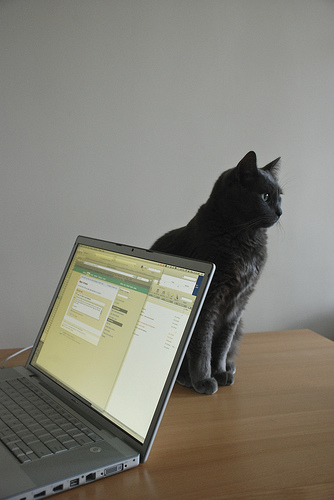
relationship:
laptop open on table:
[0, 222, 216, 491] [2, 327, 332, 499]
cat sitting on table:
[145, 149, 287, 397] [2, 327, 332, 499]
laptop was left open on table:
[0, 222, 216, 491] [2, 327, 332, 499]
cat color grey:
[145, 149, 287, 397] [141, 151, 284, 408]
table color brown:
[2, 327, 332, 499] [2, 327, 329, 495]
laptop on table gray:
[0, 222, 216, 491] [4, 374, 105, 473]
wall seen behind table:
[5, 8, 333, 339] [2, 327, 332, 499]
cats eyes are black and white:
[145, 149, 287, 397] [259, 192, 284, 204]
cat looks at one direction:
[145, 149, 287, 397] [212, 149, 298, 233]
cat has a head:
[145, 149, 287, 397] [210, 150, 291, 227]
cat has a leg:
[145, 149, 287, 397] [183, 307, 219, 398]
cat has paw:
[145, 149, 287, 397] [192, 377, 221, 395]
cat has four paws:
[145, 149, 287, 397] [181, 364, 236, 397]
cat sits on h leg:
[145, 149, 287, 397] [183, 307, 219, 398]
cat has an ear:
[145, 149, 287, 397] [237, 147, 259, 180]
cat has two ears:
[145, 149, 287, 397] [239, 151, 284, 179]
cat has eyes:
[145, 149, 287, 397] [258, 188, 283, 203]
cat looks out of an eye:
[145, 149, 287, 397] [258, 192, 271, 201]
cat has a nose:
[145, 149, 287, 397] [274, 208, 284, 216]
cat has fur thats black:
[145, 149, 287, 397] [143, 151, 292, 391]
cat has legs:
[145, 149, 287, 397] [173, 295, 243, 396]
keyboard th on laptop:
[2, 375, 107, 480] [0, 222, 216, 491]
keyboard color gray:
[1, 374, 105, 469] [4, 374, 105, 473]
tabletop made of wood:
[2, 327, 332, 499] [4, 323, 332, 498]